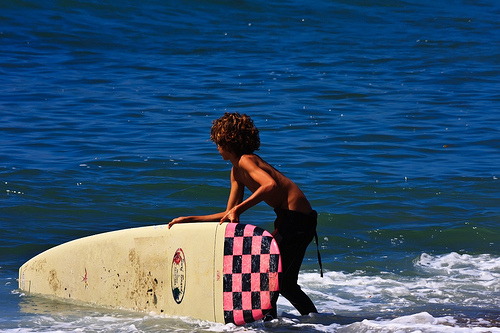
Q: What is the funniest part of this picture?
A: Wetsuit is falling down.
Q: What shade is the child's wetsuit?
A: Black.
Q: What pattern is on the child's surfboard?
A: Checkerboard.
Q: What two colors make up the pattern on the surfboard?
A: Pink and black.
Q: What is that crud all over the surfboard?
A: Sand.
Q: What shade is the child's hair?
A: Brown.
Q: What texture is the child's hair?
A: Curly.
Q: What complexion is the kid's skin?
A: Tan.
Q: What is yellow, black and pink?
A: The surfboard.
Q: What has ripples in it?
A: The water.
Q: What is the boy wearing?
A: Black pants.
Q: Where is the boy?
A: In water.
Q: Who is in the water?
A: A boy.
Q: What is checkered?
A: The board.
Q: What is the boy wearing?
A: Pants.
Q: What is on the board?
A: Pink and black checkers.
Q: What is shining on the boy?
A: The sun.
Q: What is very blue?
A: The water.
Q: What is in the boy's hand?
A: A surfboard.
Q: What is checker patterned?
A: The surfboard.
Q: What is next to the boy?
A: White suds of the ocean.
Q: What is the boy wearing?
A: Black pants.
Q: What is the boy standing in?
A: Water.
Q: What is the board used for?
A: Surfing.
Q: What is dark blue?
A: Ocean water.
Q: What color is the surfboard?
A: White.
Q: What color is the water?
A: Blue.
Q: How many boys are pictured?
A: One.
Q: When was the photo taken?
A: Daytime.